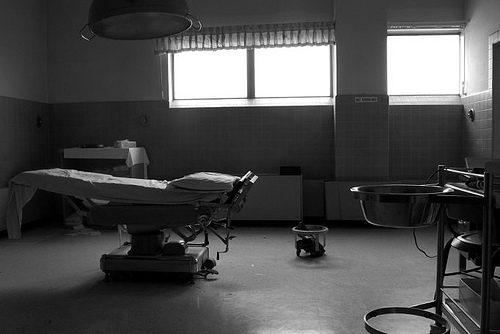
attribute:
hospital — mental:
[111, 42, 428, 296]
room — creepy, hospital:
[14, 46, 149, 117]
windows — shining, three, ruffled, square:
[171, 39, 350, 111]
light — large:
[105, 3, 126, 11]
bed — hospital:
[23, 162, 223, 210]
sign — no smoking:
[356, 93, 382, 105]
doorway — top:
[471, 25, 497, 44]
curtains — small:
[239, 28, 274, 49]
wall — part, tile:
[46, 19, 67, 29]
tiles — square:
[340, 12, 373, 24]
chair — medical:
[226, 181, 247, 216]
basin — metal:
[283, 234, 307, 249]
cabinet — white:
[128, 150, 143, 167]